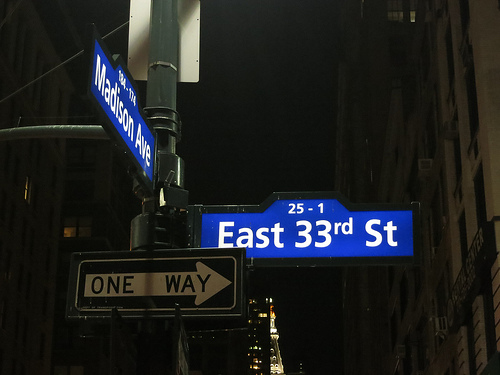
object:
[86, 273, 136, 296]
one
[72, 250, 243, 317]
sign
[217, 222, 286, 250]
east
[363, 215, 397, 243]
st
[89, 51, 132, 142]
madison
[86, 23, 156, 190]
sign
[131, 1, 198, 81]
back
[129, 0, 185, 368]
pole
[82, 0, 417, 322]
signs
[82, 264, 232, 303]
arrow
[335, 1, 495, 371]
building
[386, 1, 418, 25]
lights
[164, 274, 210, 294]
way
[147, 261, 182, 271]
black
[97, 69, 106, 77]
white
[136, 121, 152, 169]
ave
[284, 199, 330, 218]
street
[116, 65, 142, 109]
street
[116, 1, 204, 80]
above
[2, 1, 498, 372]
urban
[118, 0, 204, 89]
marker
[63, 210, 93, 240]
lit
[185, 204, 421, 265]
lit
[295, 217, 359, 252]
33rd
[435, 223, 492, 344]
sign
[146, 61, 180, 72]
strap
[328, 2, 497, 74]
top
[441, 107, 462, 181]
window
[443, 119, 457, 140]
conditioner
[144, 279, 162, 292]
white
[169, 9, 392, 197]
sky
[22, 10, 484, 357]
scene